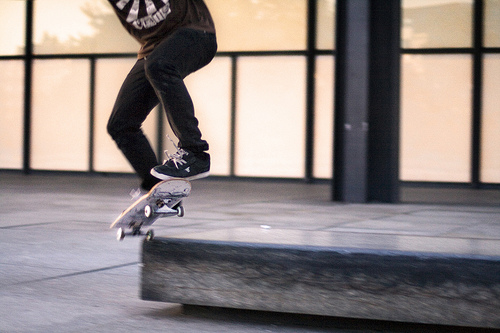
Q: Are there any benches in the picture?
A: Yes, there is a bench.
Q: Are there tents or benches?
A: Yes, there is a bench.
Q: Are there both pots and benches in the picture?
A: No, there is a bench but no pots.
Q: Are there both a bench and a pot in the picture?
A: No, there is a bench but no pots.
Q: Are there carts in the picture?
A: No, there are no carts.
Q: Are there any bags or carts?
A: No, there are no carts or bags.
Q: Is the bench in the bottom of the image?
A: Yes, the bench is in the bottom of the image.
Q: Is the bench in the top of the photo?
A: No, the bench is in the bottom of the image.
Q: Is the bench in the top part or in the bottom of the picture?
A: The bench is in the bottom of the image.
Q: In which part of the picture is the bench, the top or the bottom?
A: The bench is in the bottom of the image.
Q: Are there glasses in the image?
A: No, there are no glasses.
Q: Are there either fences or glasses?
A: No, there are no glasses or fences.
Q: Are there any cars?
A: No, there are no cars.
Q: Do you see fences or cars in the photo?
A: No, there are no cars or fences.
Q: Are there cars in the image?
A: No, there are no cars.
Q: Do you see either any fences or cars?
A: No, there are no cars or fences.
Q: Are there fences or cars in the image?
A: No, there are no cars or fences.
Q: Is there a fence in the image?
A: No, there are no fences.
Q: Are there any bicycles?
A: No, there are no bicycles.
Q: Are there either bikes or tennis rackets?
A: No, there are no bikes or tennis rackets.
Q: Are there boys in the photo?
A: No, there are no boys.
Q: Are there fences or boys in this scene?
A: No, there are no boys or fences.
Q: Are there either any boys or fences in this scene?
A: No, there are no boys or fences.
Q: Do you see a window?
A: Yes, there are windows.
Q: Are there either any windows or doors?
A: Yes, there are windows.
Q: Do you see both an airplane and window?
A: No, there are windows but no airplanes.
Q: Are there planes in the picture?
A: No, there are no planes.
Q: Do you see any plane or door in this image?
A: No, there are no airplanes or doors.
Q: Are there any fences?
A: No, there are no fences.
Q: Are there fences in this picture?
A: No, there are no fences.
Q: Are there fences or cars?
A: No, there are no fences or cars.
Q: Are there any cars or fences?
A: No, there are no fences or cars.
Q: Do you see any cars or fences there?
A: No, there are no fences or cars.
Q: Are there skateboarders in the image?
A: Yes, there is a skateboarder.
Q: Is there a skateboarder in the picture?
A: Yes, there is a skateboarder.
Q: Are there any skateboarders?
A: Yes, there is a skateboarder.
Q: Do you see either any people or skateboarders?
A: Yes, there is a skateboarder.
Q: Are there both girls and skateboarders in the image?
A: No, there is a skateboarder but no girls.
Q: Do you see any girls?
A: No, there are no girls.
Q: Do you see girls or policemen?
A: No, there are no girls or policemen.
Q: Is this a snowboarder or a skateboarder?
A: This is a skateboarder.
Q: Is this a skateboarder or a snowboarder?
A: This is a skateboarder.